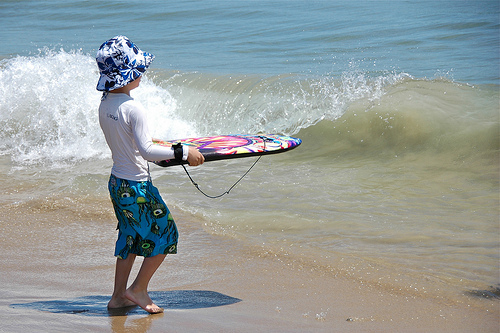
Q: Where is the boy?
A: At the beach.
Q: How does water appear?
A: Wavy.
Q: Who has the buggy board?
A: The boy.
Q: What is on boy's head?
A: Hat.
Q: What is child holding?
A: The board.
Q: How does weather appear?
A: Sunny.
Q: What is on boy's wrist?
A: Strap.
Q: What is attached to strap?
A: Board.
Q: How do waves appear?
A: Crashing.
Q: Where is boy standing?
A: In sand.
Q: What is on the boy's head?
A: A hat.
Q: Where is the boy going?
A: Toward water.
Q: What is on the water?
A: Waves.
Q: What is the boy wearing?
A: A white shirt and shorts.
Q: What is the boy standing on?
A: Sand.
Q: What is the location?
A: On the beach.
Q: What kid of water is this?
A: This is brown water.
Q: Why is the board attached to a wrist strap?
A: To prevent losing it.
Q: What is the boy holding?
A: Boogie board.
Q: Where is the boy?
A: Beach.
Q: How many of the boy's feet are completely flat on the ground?
A: One.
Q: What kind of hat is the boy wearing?
A: Bucket hat.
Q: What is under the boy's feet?
A: Sand.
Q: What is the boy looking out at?
A: The ocean.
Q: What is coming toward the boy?
A: A wave.